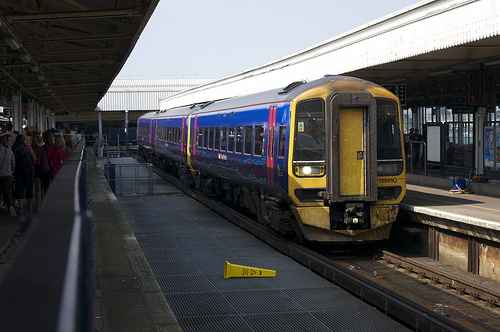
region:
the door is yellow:
[313, 98, 424, 246]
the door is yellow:
[326, 117, 378, 227]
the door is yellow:
[312, 75, 374, 176]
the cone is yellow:
[243, 249, 252, 294]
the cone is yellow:
[254, 255, 270, 290]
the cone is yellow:
[253, 258, 263, 290]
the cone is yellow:
[247, 255, 259, 285]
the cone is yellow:
[244, 263, 256, 288]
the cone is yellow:
[239, 245, 261, 292]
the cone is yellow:
[249, 273, 259, 276]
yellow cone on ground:
[207, 261, 282, 280]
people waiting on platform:
[3, 117, 81, 245]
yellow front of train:
[293, 91, 405, 246]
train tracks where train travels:
[319, 257, 499, 330]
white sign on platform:
[422, 113, 443, 178]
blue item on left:
[442, 174, 473, 204]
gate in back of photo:
[90, 120, 131, 151]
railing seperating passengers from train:
[64, 109, 101, 327]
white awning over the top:
[96, 85, 156, 117]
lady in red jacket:
[46, 127, 71, 175]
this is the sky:
[169, 22, 233, 62]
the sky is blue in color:
[165, 20, 230, 62]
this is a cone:
[223, 257, 278, 282]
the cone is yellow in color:
[229, 264, 240, 276]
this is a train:
[132, 73, 404, 240]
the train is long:
[135, 75, 422, 245]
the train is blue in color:
[240, 106, 265, 124]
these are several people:
[3, 121, 62, 179]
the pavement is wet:
[108, 160, 164, 206]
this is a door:
[338, 104, 373, 201]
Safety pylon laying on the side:
[220, 253, 286, 282]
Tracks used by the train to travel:
[374, 255, 450, 315]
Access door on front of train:
[328, 98, 374, 200]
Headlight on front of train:
[285, 160, 330, 182]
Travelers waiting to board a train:
[15, 121, 80, 193]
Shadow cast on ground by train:
[415, 183, 490, 213]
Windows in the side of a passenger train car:
[190, 123, 270, 158]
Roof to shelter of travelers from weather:
[0, 11, 159, 116]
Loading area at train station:
[404, 83, 496, 230]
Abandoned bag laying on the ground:
[438, 166, 478, 207]